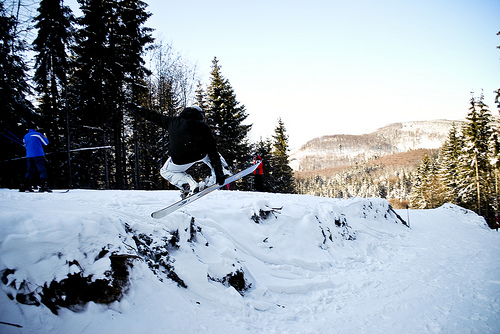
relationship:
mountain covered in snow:
[298, 118, 498, 193] [396, 117, 454, 147]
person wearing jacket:
[10, 117, 59, 192] [23, 130, 44, 157]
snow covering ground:
[385, 243, 483, 323] [3, 178, 483, 318]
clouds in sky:
[248, 25, 363, 100] [6, 4, 485, 197]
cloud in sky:
[183, 8, 473, 146] [316, 22, 383, 76]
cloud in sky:
[183, 8, 473, 146] [161, 3, 498, 125]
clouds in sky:
[248, 25, 363, 100] [6, 3, 499, 151]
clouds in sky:
[184, 7, 209, 36] [1, 1, 496, 168]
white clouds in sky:
[366, 30, 429, 60] [1, 1, 496, 168]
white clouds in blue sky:
[366, 30, 429, 60] [2, 0, 498, 147]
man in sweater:
[123, 96, 234, 197] [135, 101, 230, 180]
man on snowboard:
[123, 96, 234, 197] [135, 153, 252, 221]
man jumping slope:
[123, 96, 234, 197] [3, 175, 484, 322]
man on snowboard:
[123, 96, 234, 197] [139, 159, 273, 222]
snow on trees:
[454, 141, 481, 202] [468, 94, 498, 216]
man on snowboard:
[123, 96, 234, 197] [140, 150, 266, 222]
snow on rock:
[110, 209, 191, 244] [10, 212, 232, 324]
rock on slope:
[10, 212, 232, 324] [7, 183, 499, 332]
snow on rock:
[200, 254, 260, 301] [340, 196, 408, 231]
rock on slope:
[340, 196, 408, 231] [3, 175, 484, 322]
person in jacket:
[10, 117, 59, 192] [22, 127, 48, 161]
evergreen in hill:
[267, 117, 297, 192] [246, 185, 342, 223]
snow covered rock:
[398, 207, 467, 256] [340, 196, 408, 231]